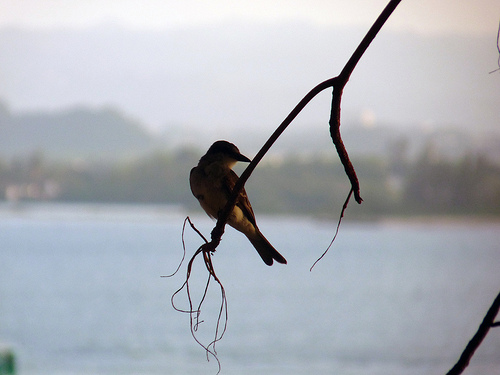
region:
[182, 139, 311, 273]
One brown bird sitting on a branch.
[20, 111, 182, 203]
Blurry hilly background.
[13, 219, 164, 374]
Blue body of water.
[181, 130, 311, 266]
Small bird looking for food.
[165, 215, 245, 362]
Six small twigs on tip of branch.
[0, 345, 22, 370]
Green blurry object.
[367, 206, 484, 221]
Tan blurry shoreline.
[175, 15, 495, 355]
Two medium branches.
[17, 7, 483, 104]
Blurry skyline.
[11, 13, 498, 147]
Mountain shadows in background.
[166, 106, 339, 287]
Bird on the branch.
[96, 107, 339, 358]
Bird near the water.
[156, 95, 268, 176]
Bird head with a beak.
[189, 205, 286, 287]
Bird's feet gripping the branch.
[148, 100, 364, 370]
Limb with no leaves.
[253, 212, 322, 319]
Bird tail feathers.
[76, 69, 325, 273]
Mountains and trees in the distance.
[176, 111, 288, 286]
Bird resting on a tree limb.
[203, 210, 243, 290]
Bird gripping the twig with it's feet.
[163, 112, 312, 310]
Bird overlooking the water.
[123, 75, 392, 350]
a bird on a limb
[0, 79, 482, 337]
a bird in front of a lake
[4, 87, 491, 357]
a bird with a lake in the background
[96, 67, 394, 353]
a bird on a branch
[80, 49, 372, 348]
a bird on a leafless limb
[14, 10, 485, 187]
a haze in the distance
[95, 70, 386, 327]
a bird looking to the right of the photo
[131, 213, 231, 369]
stringy appendages to a tree limb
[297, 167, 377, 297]
a lonely twig attached to a branch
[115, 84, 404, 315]
a bird with a sharp beak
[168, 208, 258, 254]
Bird's feet gripping a limb.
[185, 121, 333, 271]
Bird over watching the water outdoors.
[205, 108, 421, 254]
Tree branch with no leaves.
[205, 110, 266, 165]
Bird beak.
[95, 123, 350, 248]
Trees along the water in the background.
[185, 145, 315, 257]
Bird's feathers.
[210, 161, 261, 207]
Bird wing.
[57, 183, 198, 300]
Lake in the background.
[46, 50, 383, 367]
this a lovely bird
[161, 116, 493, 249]
a bird on the tree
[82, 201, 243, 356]
this is a lake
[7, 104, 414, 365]
what a lovely shot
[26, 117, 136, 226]
this are hills on the background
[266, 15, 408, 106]
this is a tree branch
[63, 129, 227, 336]
i love this specific view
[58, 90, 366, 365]
this is a lovely photo indeed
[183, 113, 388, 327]
the bird is very pretty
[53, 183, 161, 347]
this a blue lake